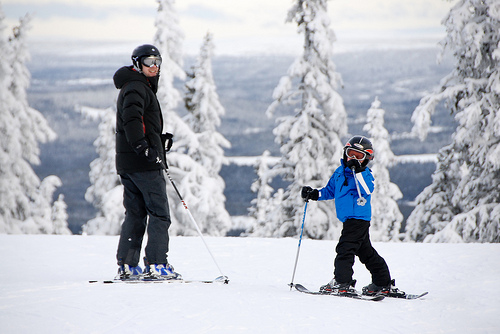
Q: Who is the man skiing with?
A: The son.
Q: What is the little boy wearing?
A: A blue parka.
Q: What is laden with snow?
A: Tree.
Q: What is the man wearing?
A: Black ski jacket.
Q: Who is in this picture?
A: A man and a child.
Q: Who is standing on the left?
A: Man wearing black coat.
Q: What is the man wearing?
A: Black helmet.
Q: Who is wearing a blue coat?
A: A small child.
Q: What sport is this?
A: Skiing.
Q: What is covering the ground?
A: Snow.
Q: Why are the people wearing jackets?
A: It is cold.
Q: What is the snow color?
A: White.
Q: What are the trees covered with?
A: Snow.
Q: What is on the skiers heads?
A: Helmets.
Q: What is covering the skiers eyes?
A: Goggles.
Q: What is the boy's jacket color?
A: Blue.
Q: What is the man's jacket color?
A: Black.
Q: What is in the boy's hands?
A: Ski Poles.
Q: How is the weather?
A: Cold.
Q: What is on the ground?
A: Snow.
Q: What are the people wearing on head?
A: Helmet.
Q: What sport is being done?
A: Skiing.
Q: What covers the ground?
A: Snow.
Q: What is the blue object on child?
A: Jacket.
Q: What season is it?
A: Winter.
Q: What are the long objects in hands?
A: Poles.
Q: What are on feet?
A: Skis.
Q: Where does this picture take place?
A: On a ski slope.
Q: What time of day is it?
A: Daytime.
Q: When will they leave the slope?
A: When they are finished skiing.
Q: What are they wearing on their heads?
A: Helmets.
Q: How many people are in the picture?
A: Two.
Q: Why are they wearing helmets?
A: To protect their heads in case of an accident.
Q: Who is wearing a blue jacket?
A: The boy.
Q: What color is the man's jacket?
A: Black.